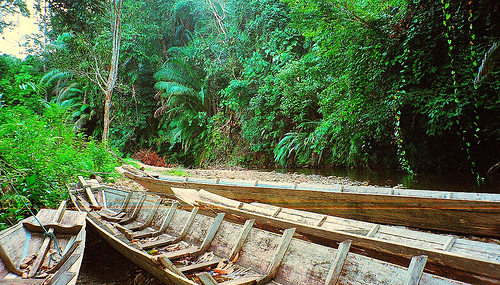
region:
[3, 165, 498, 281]
Wooden boats in a jungle.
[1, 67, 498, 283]
Torn wooden boats on the ground in the jungle.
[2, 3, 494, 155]
Green plants and trees in the jungle.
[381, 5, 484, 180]
Green vines with leave on a tall bush.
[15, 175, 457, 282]
Dirty boat with debris inside.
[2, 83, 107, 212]
Green bush behind two boats.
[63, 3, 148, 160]
Tree with green leaves in the jungle.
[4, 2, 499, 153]
Green natural features in the jungle.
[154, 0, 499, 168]
Green plants and trees beside a path.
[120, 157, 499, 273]
Two torn boats in the jungle.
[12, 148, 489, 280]
4 wooden boats on shore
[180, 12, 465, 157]
forest filled with lush green trees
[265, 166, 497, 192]
river along tree line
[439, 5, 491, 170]
light green ivy cascading down from trees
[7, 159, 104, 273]
blue rope tying boat to shore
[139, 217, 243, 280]
colorful leaves on boat floor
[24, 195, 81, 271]
oar used to maneuver boat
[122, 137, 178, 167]
small bush with red leaves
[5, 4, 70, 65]
bright sky peeking through trees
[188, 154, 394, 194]
rock shore along river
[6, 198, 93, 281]
first boat on the left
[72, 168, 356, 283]
second boat from left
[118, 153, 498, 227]
boat in upper right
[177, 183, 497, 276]
second boat on right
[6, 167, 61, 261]
rope holding boat to shore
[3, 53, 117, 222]
green vegetation to left of picture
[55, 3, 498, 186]
trees and brush in upper portion of picture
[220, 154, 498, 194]
body of water near boats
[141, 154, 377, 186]
small empty beach area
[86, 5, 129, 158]
tree with no leaves on left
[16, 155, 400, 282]
canoes abandoned in the forest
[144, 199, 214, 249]
wooden slats in a a boat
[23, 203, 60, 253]
blue rope in the boat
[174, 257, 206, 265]
dead leaves in the boat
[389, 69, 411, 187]
a long vine of ivy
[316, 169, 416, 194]
dark river water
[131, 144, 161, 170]
a patch of red flowers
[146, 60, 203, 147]
large green ferns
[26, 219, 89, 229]
a wooden foot rest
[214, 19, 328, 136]
trees growing along the river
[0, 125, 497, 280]
Boats laying on a field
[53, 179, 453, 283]
Boats are wood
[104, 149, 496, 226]
Boat is large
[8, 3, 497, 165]
Trees in a forest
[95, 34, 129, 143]
Trunk of a tree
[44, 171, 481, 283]
Boat looks old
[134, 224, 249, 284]
Dry leaves inside of boat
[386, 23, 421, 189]
Vine hanging from a tree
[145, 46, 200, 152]
Big leaves of a tree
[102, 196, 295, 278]
Pieces of wood in the boat